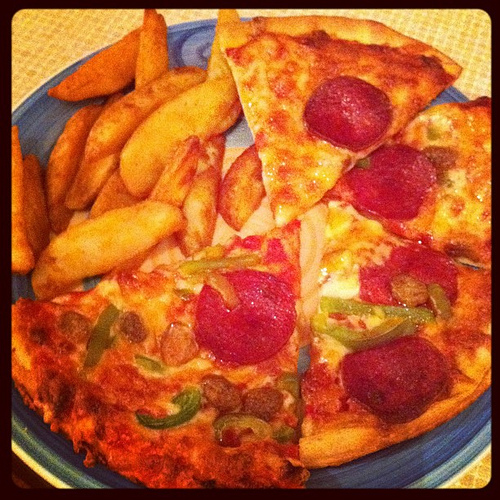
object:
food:
[73, 68, 443, 422]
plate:
[11, 16, 490, 488]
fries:
[13, 119, 231, 251]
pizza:
[214, 15, 464, 230]